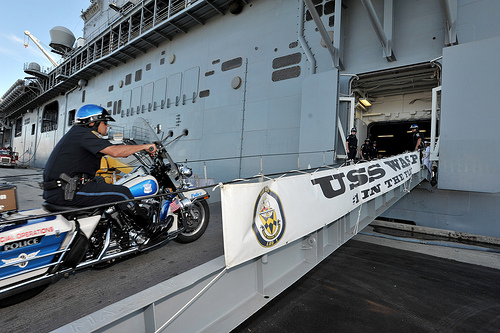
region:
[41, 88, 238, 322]
police officer on motorcycle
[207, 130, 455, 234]
white USS WASP banner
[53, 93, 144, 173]
officer wearing blue helmet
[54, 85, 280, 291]
officer riding motorcycle up ramp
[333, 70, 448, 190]
three officers standing by door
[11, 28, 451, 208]
silver boat with boat ramp in photo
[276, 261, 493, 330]
water visible in photo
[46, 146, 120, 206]
officer wearing gun on his side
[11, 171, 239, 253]
blue and white motorcycle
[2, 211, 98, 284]
motorcycle says special operations in red letters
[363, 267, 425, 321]
dark black ocean water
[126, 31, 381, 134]
light gray boat in water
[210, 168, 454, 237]
white banner on boat ramp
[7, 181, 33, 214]
brown cardboard box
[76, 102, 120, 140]
light blue metallic helmet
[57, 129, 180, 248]
police offer riding a motorcycle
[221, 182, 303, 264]
USS emblem on banner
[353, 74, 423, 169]
entryway to the boat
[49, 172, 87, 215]
black gun on the holster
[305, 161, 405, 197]
The letters USS on a white banner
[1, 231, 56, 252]
White POLICE letters on a black sign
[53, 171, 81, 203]
Policeman's side arm on his right side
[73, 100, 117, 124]
Blue helmet on a man's head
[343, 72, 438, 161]
Four policeman standing in a doorway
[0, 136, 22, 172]
Red truck parked in front of a building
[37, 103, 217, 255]
Policeman sitting on a motorcycle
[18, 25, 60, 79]
White crane on top of a building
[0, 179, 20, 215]
Closed cardboard box white white stickers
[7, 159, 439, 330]
Ramp leading into a building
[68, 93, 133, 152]
Person is wearing blue helmet.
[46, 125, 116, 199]
Person is wearing black shirt.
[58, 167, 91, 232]
Person has gun on belt.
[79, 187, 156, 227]
Blue stripe down side of pants.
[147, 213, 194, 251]
Person has black boots on.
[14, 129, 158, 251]
Person sitting on bike.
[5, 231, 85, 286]
Bike says Police on side.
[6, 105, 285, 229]
Person riding bike on to boat.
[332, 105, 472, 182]
People in doorway of large ship.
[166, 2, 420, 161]
Large ship is gray in color.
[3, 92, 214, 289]
Call operations Harley Davidson motorcycle.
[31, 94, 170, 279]
Call operations policeman on motorcycle.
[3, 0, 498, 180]
Military ship.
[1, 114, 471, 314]
Ship gangplank for loading and unloading of passengers and materials.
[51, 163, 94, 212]
Handgun used for protection and to apprehend criminals.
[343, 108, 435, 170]
Policeman awaiting motorcycle arrival.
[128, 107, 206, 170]
Mooring lines and cables.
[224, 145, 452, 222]
Ship identification banner.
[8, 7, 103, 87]
Ship's radar stations.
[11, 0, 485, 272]
Port side of the ship.